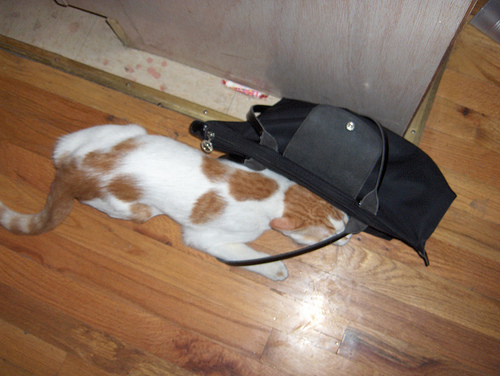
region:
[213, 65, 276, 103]
roll of smarties on the floor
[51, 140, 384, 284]
cat is laying in the handle of the purse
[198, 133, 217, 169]
zipper pull on the purse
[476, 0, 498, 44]
clear plastic cup on the floor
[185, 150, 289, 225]
brown spots on the cat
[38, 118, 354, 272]
brown and white cat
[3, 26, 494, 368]
wooden floor made out of slats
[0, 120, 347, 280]
brown and white cat lying on floor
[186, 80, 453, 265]
wide black bag with leather flap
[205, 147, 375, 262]
handbag strap across paw and head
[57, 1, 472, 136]
gray wall with tan scratch marks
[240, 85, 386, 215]
black strap underneath bag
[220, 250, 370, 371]
reflection of light on floor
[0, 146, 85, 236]
cat's striped tail curved along floor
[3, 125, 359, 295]
a colorful cat laying on the floor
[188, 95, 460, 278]
the bag the cat is laying by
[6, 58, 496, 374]
the wooden floor the cat is laying on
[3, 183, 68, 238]
the striped tail of the cat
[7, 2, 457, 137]
the wall next to the cat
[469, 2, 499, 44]
a plastic container on the floor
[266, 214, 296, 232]
the ear of the kitty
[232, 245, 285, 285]
the paw of the kitty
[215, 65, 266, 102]
a candy sitting by the wall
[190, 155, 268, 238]
the spots on the kitty's back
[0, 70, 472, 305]
a cat sleeping under a purse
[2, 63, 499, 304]
a cat taking a nap under a purse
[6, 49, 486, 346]
a cat taking a nap under a handbag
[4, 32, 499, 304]
a cat taking a nap under a lady's handbag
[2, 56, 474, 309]
cat relaxing under a handbag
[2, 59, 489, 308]
cat relaxing under a purse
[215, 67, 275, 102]
a red crayon on the floor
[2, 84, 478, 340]
red and white cat sleeping under a black handbag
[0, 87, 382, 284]
a ginger and white cat sleeping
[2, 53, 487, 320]
cat having a rest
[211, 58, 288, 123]
roll of smarties on the floor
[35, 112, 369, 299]
brown and white cat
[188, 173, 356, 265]
cat is laying in the handle of the purse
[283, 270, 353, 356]
light reflection in the floor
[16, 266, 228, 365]
wood flooring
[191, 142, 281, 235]
brown spots on the cat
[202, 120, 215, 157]
zipper pull on the purse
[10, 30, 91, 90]
metal edge trim on the floor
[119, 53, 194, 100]
spots on the tile floor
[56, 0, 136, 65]
edge of the cabinet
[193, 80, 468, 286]
A black pocketbook.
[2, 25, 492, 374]
Brown hardwood floors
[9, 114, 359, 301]
A white cat with orange spots.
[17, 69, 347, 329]
a cat on the floor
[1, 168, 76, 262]
a tail on the cat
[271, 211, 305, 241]
an ear on the cat